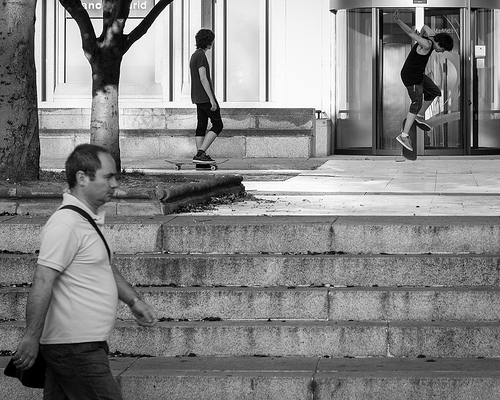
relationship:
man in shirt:
[24, 141, 156, 391] [32, 196, 131, 337]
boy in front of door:
[382, 9, 459, 166] [363, 3, 484, 157]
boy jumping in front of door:
[382, 9, 459, 166] [363, 3, 484, 157]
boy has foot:
[382, 9, 459, 166] [397, 128, 427, 158]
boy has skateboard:
[382, 9, 459, 166] [401, 112, 419, 166]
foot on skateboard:
[397, 128, 427, 158] [401, 112, 419, 166]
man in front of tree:
[24, 141, 156, 391] [59, 3, 154, 180]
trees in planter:
[2, 1, 139, 182] [9, 151, 241, 219]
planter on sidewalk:
[9, 151, 241, 219] [223, 165, 469, 230]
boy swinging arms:
[382, 9, 459, 166] [395, 12, 435, 52]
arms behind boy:
[395, 12, 435, 52] [382, 9, 459, 166]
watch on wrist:
[125, 294, 141, 307] [126, 293, 152, 310]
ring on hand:
[16, 356, 28, 362] [9, 325, 44, 379]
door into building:
[363, 3, 484, 157] [172, 5, 394, 155]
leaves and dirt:
[216, 191, 250, 213] [265, 195, 299, 215]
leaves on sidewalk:
[216, 191, 250, 213] [223, 165, 469, 230]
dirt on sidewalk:
[265, 195, 299, 215] [223, 165, 469, 230]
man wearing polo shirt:
[24, 141, 156, 391] [32, 196, 131, 337]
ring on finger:
[16, 356, 28, 362] [19, 350, 25, 370]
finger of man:
[19, 350, 25, 370] [24, 141, 156, 391]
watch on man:
[125, 294, 141, 307] [24, 141, 156, 391]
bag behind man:
[13, 336, 53, 399] [24, 141, 156, 391]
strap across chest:
[57, 204, 113, 249] [60, 225, 120, 304]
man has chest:
[24, 141, 156, 391] [60, 225, 120, 304]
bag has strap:
[13, 336, 53, 399] [57, 204, 113, 249]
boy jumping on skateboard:
[382, 9, 459, 166] [401, 112, 419, 166]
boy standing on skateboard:
[191, 32, 243, 158] [167, 152, 232, 171]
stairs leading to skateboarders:
[272, 209, 433, 370] [172, 5, 394, 155]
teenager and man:
[191, 32, 243, 158] [24, 141, 156, 391]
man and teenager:
[24, 141, 156, 391] [191, 32, 243, 158]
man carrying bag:
[24, 141, 156, 391] [13, 336, 53, 399]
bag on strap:
[13, 336, 53, 399] [57, 204, 113, 249]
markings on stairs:
[150, 252, 226, 294] [272, 320, 426, 358]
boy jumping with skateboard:
[382, 9, 459, 166] [401, 112, 419, 166]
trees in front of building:
[2, 1, 139, 182] [172, 5, 394, 155]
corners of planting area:
[153, 171, 245, 213] [9, 151, 241, 219]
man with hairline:
[24, 141, 156, 391] [89, 142, 120, 168]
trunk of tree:
[89, 65, 133, 162] [59, 3, 154, 180]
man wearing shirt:
[24, 141, 156, 391] [32, 196, 131, 337]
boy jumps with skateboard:
[382, 9, 459, 166] [401, 112, 419, 166]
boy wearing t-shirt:
[382, 9, 459, 166] [184, 51, 224, 112]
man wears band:
[24, 141, 156, 391] [126, 293, 152, 310]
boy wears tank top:
[382, 9, 459, 166] [403, 37, 434, 88]